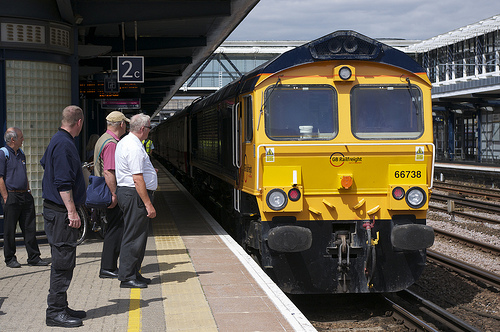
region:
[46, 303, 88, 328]
Man is wearing shoes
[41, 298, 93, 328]
Man is wearing black shoes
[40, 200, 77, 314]
Man is wearing pants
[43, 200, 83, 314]
Man is wearing black pants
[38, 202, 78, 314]
Man is wearing cargo pants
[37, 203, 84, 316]
Man is wearing black cargo pants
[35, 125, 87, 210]
Man is wearing a sweatshirt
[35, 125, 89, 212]
Man is wearing a blue sweatshirt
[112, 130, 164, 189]
Man is wearing a white shirt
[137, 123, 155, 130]
Man is wearing sunglasses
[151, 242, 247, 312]
The ground is made of concrete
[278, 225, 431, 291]
The bottom of the train is black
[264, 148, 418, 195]
The top of the bus is the color yellow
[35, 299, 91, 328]
The feet of the man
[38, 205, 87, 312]
The man is wearing black pants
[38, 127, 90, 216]
The man is wearing a blue shirt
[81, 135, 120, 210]
The man is holding a blue bag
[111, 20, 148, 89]
The sign hanging from the ceiling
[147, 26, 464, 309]
The train on the train tracks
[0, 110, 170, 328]
The people waiting for the train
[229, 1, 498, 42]
a lot of clouds in the sky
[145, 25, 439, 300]
a yellow train stopping for passengers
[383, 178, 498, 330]
a set of train tracks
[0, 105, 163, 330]
a group of people waiting to get on the train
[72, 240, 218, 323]
shadows being cast by the people waiting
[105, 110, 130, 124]
a baseball hat on the man's head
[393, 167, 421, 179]
the number 66738 on the front of the train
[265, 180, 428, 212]
headlights on the front of the train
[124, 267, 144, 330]
a yellow light painted on the waiting platform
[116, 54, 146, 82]
a sign that says 2c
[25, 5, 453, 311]
commuters waiting on an arriving train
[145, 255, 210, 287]
shadows of two men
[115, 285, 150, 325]
yellow caution line on the platform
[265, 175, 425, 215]
headlights of the first car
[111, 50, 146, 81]
number of the train platform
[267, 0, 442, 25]
cloudy sky above the station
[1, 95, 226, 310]
passengers standing back from the edge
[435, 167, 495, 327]
train rails going in both directions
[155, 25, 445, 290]
commuter train arriving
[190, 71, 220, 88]
portion of pedestrian overpass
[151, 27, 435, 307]
yellow train pulling into the train station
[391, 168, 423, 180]
number in the front of the train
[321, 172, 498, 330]
train tracks with gravel in between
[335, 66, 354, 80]
light on the train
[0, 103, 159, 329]
people waiting for the train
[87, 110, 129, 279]
man with a duffle bag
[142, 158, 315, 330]
sidewalk in front of the depot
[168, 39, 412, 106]
walk-way from one building to the other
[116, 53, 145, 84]
sign in front of the train station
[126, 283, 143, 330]
yellow line for people to stand behind